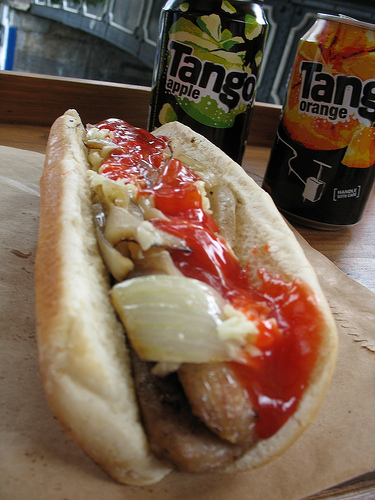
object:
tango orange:
[299, 62, 374, 122]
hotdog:
[32, 108, 338, 488]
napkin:
[323, 339, 375, 482]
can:
[147, 0, 270, 167]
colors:
[201, 109, 228, 127]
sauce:
[262, 291, 308, 357]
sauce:
[273, 291, 305, 339]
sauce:
[263, 383, 284, 412]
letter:
[219, 71, 249, 109]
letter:
[301, 62, 323, 99]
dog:
[38, 109, 333, 476]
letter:
[169, 40, 193, 77]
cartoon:
[276, 130, 330, 203]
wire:
[277, 133, 305, 184]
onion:
[111, 274, 259, 362]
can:
[260, 13, 374, 231]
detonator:
[302, 160, 331, 202]